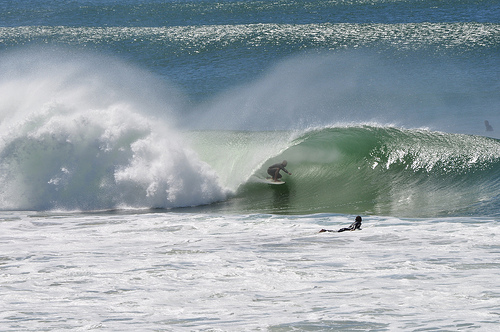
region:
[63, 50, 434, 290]
two people in the water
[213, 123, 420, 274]
a person surf boarding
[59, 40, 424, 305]
a large wave of water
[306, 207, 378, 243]
person paddling in water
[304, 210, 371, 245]
person paddling in water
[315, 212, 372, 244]
person paddling in water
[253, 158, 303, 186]
SURFER UNDER ARCH OF WAVE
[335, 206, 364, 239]
SECOND SURFER IN FRONT OF WAVE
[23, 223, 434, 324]
WHITE FOAM ON ROUGH OCEAN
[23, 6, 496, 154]
MORE WAVES IN THE DISTANCE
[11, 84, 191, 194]
MIST AND SPRAY COMING OFF WAVE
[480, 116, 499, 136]
BIRD FLYING CLOSE TO THE WATER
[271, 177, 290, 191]
WHITE SURFBOARD IN WATER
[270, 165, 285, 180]
RIGHT LEG OF SURFER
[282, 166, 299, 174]
RIGHT ARM OF SURFER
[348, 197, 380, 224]
HEAD OF SECOND SURFER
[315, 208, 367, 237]
girl laying on surfboard in the surf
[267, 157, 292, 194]
person on surfboard under wave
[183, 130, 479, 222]
wave coming in to shore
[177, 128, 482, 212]
it looks like a green circle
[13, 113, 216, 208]
rough water made by the power of the wave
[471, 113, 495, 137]
person on a surfboard behind the wave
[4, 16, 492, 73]
water droplets shot up in the sky by the power of the wave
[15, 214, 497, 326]
the water is white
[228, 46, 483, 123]
spray from the water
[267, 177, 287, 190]
the surfboard is white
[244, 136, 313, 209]
surfer on a wave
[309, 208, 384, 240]
person laying in the surf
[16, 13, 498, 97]
giant wave in the ocean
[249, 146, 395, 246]
two surfers in the ocean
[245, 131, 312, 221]
surfer hanging ten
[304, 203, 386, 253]
person laying down on the beach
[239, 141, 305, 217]
man on a white surfboard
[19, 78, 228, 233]
white foam on the wave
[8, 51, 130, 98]
white spray from the ocean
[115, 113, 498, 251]
trio of surfers on the ocean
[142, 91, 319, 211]
surfer enjoying some waves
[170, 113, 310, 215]
surfer enjoying some awesome waves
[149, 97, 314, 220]
surfer enjoying some huge waves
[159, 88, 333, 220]
surfer enjoying some beautiful waves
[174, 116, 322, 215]
surfer enjoying some massive waves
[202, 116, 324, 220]
surfer enjoying some attractive waves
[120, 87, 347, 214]
surfer enjoying some great waves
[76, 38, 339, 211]
surfer enjoying some amazing waves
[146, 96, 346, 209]
surfer enjoying some ocean waves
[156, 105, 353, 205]
surfer enjoying perfect ocean waves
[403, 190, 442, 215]
part of a ocean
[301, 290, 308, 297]
part of the ocean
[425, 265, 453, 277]
ripples of water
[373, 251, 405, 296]
part of the sea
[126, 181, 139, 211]
edge of a wave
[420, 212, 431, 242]
top of a huge water wave